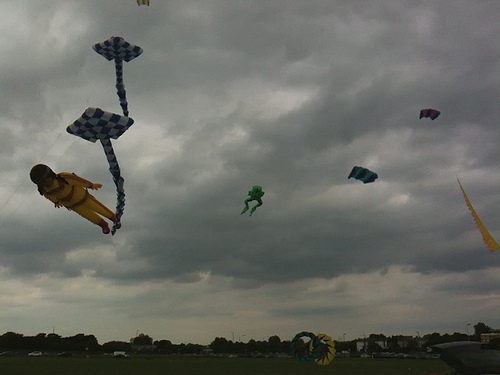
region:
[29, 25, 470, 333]
many kites in sky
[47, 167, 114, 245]
red and yellow person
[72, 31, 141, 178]
black and white checked kites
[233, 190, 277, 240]
green kite in distance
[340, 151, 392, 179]
black and blue kite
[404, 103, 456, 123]
blue and yellow kite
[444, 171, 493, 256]
long an yellow kite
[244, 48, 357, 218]
grey and white sky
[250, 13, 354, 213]
heavy clouds in sky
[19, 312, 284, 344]
green trees in far distance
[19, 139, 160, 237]
kite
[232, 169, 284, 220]
kite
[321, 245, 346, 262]
white clouds in blue sky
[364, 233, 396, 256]
white clouds in blue sky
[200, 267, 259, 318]
white clouds in blue sky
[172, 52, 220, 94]
white clouds in blue sky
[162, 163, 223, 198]
white clouds in blue sky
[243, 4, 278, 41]
white clouds in blue sky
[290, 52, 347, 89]
white clouds in blue sky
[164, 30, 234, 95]
white clouds in blue sky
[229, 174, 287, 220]
A kite that looks like a kite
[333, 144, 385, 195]
A blue kite in the air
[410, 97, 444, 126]
A red and blue kite in the air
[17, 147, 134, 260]
A kite that looks like a doll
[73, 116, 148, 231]
A blue and white checkered kite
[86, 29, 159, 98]
A higher blue and white checkered kite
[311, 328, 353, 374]
A yellow colored circle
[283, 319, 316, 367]
A green colored circle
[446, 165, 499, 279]
A yellow kites tail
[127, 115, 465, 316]
A cloudy looking sky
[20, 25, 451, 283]
A variety of kites gliding in the air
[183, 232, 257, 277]
a soggy cloudy sky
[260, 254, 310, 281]
a soggy cloudy sky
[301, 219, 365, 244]
a soggy cloudy sky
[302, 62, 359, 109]
a soggy cloudy sky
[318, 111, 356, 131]
a soggy cloudy sky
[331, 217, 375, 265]
a soggy cloudy sky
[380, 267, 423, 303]
a soggy cloudy sky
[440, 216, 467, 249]
a soggy cloudy sky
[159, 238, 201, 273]
a soggy cloudy sky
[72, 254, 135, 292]
a soggy cloudy sky